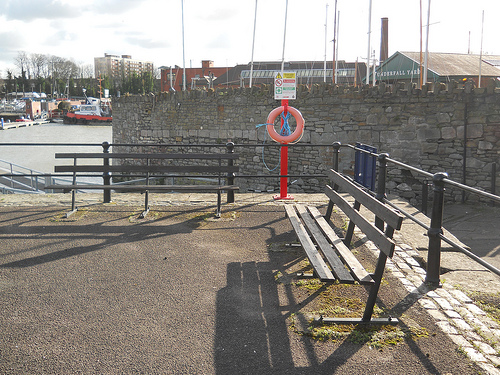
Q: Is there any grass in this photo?
A: Yes, there is grass.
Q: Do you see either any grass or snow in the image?
A: Yes, there is grass.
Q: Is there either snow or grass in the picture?
A: Yes, there is grass.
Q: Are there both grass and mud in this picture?
A: No, there is grass but no mud.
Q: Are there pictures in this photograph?
A: No, there are no pictures.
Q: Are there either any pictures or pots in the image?
A: No, there are no pictures or pots.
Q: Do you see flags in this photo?
A: No, there are no flags.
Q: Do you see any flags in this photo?
A: No, there are no flags.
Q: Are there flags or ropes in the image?
A: No, there are no flags or ropes.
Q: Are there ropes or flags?
A: No, there are no flags or ropes.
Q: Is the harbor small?
A: Yes, the harbor is small.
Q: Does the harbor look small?
A: Yes, the harbor is small.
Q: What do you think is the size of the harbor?
A: The harbor is small.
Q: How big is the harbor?
A: The harbor is small.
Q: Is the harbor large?
A: No, the harbor is small.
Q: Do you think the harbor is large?
A: No, the harbor is small.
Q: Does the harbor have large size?
A: No, the harbor is small.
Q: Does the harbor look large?
A: No, the harbor is small.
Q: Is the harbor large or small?
A: The harbor is small.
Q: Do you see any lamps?
A: No, there are no lamps.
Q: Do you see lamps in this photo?
A: No, there are no lamps.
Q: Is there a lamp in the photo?
A: No, there are no lamps.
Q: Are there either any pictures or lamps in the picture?
A: No, there are no lamps or pictures.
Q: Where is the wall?
A: The wall is in the harbor.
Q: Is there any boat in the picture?
A: Yes, there is a boat.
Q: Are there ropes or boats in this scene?
A: Yes, there is a boat.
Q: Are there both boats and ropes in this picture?
A: No, there is a boat but no ropes.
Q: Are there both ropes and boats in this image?
A: No, there is a boat but no ropes.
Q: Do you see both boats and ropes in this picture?
A: No, there is a boat but no ropes.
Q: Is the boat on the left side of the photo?
A: Yes, the boat is on the left of the image.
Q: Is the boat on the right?
A: No, the boat is on the left of the image.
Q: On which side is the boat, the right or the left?
A: The boat is on the left of the image.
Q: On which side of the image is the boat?
A: The boat is on the left of the image.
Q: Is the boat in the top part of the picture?
A: Yes, the boat is in the top of the image.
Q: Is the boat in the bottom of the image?
A: No, the boat is in the top of the image.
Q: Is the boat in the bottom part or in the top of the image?
A: The boat is in the top of the image.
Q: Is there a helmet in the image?
A: No, there are no helmets.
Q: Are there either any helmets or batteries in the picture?
A: No, there are no helmets or batteries.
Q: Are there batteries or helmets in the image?
A: No, there are no helmets or batteries.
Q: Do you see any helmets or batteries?
A: No, there are no helmets or batteries.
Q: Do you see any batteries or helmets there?
A: No, there are no helmets or batteries.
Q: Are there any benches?
A: Yes, there is a bench.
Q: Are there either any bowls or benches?
A: Yes, there is a bench.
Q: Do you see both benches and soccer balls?
A: No, there is a bench but no soccer balls.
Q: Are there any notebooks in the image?
A: No, there are no notebooks.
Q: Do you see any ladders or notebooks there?
A: No, there are no notebooks or ladders.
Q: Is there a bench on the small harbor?
A: Yes, there is a bench on the harbor.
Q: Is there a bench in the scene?
A: Yes, there is a bench.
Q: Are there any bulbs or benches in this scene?
A: Yes, there is a bench.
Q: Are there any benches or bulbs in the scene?
A: Yes, there is a bench.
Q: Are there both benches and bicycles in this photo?
A: No, there is a bench but no bicycles.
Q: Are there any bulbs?
A: No, there are no bulbs.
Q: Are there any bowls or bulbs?
A: No, there are no bulbs or bowls.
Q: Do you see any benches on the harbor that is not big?
A: Yes, there is a bench on the harbor.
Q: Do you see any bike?
A: No, there are no bikes.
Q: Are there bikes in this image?
A: No, there are no bikes.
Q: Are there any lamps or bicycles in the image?
A: No, there are no bicycles or lamps.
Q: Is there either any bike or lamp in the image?
A: No, there are no bikes or lamps.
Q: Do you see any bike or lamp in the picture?
A: No, there are no bikes or lamps.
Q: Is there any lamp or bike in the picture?
A: No, there are no bikes or lamps.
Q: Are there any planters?
A: No, there are no planters.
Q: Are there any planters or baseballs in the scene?
A: No, there are no planters or baseballs.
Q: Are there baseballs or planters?
A: No, there are no planters or baseballs.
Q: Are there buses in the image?
A: No, there are no buses.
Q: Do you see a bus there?
A: No, there are no buses.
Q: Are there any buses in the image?
A: No, there are no buses.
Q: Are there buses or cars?
A: No, there are no buses or cars.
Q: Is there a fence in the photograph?
A: Yes, there is a fence.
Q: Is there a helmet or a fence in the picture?
A: Yes, there is a fence.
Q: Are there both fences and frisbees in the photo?
A: No, there is a fence but no frisbees.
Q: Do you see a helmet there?
A: No, there are no helmets.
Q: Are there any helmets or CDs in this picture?
A: No, there are no helmets or cds.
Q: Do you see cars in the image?
A: No, there are no cars.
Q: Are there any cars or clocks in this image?
A: No, there are no cars or clocks.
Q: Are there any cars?
A: No, there are no cars.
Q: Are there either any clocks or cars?
A: No, there are no cars or clocks.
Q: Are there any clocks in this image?
A: No, there are no clocks.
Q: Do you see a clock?
A: No, there are no clocks.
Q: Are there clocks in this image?
A: No, there are no clocks.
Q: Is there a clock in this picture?
A: No, there are no clocks.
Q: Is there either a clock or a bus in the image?
A: No, there are no clocks or buses.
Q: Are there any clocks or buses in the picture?
A: No, there are no clocks or buses.